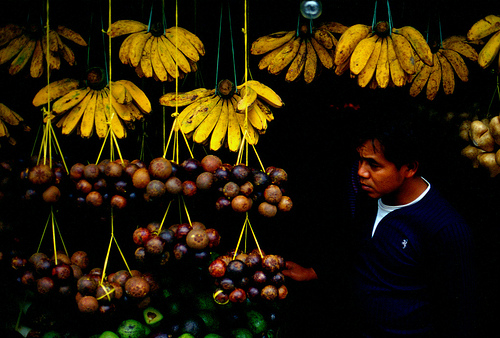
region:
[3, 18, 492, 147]
bunches of ripe plantains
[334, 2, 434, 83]
plantains hanging from blue cord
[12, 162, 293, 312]
fruit hanging from yellow cords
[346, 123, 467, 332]
man looking at hanging fruit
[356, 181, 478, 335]
blue shirt on man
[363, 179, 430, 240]
white shirt under blue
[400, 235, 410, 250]
white emblem on shirt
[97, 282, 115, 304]
yellow cord around fruit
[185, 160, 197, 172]
light reflection on fruit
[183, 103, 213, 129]
discoloration on yellow skin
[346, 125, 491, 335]
man touching round reddish fruit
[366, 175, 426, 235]
white tshirt under blue sweater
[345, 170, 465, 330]
navy blue sweater on man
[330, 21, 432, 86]
yellow bunch of bananas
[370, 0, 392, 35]
green string holding bunch of bananas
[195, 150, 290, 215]
bunch of reddish fruit hanging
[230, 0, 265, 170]
yellow string holding reddish fruit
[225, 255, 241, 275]
purplish round fruit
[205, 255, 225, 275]
bright red fruit next to purplish fruit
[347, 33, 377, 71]
ripe yellow banana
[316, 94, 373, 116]
tiny orange light behind fruit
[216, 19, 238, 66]
tall green rope on fruit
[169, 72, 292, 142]
yellow bananas on string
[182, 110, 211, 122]
brown blemish on banana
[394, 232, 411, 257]
white logo on man's shirt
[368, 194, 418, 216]
collar of white shirt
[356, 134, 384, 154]
black hair in man's face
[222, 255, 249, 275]
small shiny black fruit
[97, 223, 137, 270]
yellow string holding fruit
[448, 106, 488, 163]
potatoes in a bunch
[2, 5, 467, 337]
A man looking at fruit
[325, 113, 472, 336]
a man in a blue shirt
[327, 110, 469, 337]
a man with dark hair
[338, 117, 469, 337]
a man looking left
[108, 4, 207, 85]
bananas hanging by a string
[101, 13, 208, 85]
Many yellow fruits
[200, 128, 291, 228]
Purple fruit hanging by a string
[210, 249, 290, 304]
Many purple fruits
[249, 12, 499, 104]
A group of bananas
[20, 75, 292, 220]
Different fruits hanging together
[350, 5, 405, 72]
A banch ripe bananas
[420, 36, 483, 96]
A banch ripe bananas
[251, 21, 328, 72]
A banch ripe bananas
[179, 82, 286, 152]
A banch ripe bananas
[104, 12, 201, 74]
A banch ripe bananas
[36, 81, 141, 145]
A banch ripe bananas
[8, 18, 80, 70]
A banch ripe bananas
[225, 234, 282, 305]
A banch ripe passion fruits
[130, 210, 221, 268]
A banch ripe passion fruits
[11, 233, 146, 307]
A banch ripe passion fruits